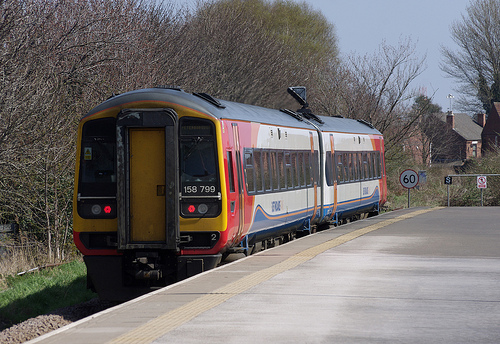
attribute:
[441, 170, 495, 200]
fencing — metal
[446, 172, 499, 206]
fence — metal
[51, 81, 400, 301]
train — short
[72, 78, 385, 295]
train — white, red, orange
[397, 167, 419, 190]
sign — white, round 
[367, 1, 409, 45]
sky — clear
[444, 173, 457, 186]
sign — black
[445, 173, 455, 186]
number — white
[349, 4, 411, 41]
sky — clear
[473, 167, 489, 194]
sign — white, red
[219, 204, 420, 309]
line — yellow